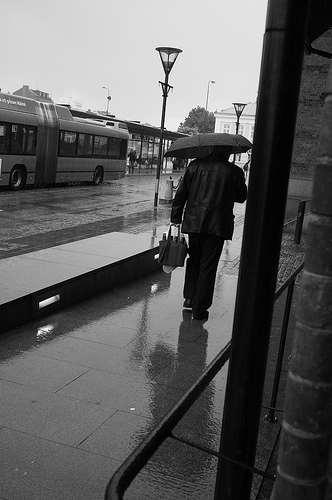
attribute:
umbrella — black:
[159, 132, 253, 159]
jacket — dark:
[166, 152, 248, 240]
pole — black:
[151, 44, 182, 216]